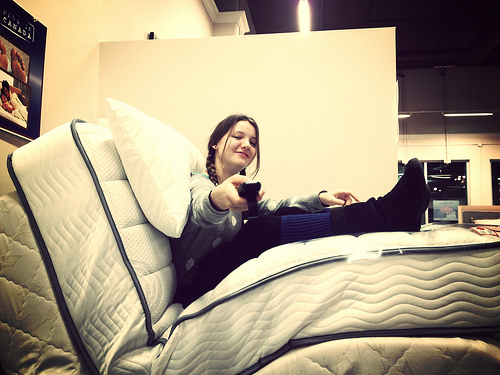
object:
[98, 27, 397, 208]
wall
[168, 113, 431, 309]
girl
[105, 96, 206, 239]
pillow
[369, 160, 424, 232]
sock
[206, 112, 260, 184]
hair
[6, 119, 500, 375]
mattress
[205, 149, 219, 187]
pigtails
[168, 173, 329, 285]
shirt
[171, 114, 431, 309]
woman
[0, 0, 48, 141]
picture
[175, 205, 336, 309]
pant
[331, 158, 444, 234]
shoe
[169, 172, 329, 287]
sweater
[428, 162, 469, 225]
window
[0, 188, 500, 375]
bed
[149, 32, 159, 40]
fixture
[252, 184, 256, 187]
remote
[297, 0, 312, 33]
light